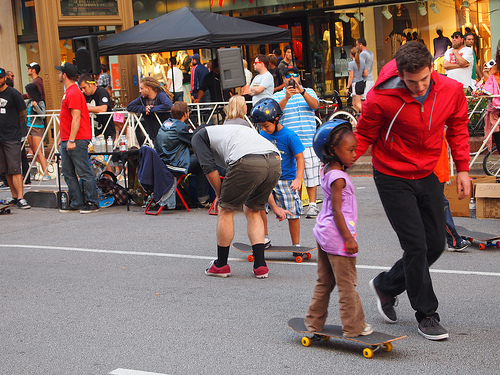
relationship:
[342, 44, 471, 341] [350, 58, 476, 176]
man wearing a jacket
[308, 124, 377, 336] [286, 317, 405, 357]
girl riding skateboard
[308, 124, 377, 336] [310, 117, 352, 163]
girl wearing a helmet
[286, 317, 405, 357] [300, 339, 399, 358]
skateboard has yellow wheels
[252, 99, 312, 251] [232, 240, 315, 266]
boy on skateboard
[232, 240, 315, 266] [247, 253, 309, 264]
skateboard has red wheels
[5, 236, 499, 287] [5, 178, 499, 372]
line on street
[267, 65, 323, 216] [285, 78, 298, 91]
man holding cellphone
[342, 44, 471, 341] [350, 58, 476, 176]
man in a jacket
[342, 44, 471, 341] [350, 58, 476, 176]
man in jacket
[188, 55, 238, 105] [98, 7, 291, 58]
person under canopy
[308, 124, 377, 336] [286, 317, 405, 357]
girl on skateboard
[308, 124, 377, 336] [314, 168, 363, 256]
girl wearing shirt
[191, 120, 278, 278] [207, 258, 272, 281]
man wearing shoes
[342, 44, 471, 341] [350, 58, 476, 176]
man wearing jacket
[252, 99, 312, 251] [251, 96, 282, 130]
boy wearing a helmet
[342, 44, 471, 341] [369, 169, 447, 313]
man wearing pants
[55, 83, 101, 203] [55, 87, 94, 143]
man wearing shirt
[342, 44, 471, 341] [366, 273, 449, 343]
man wearing shoes